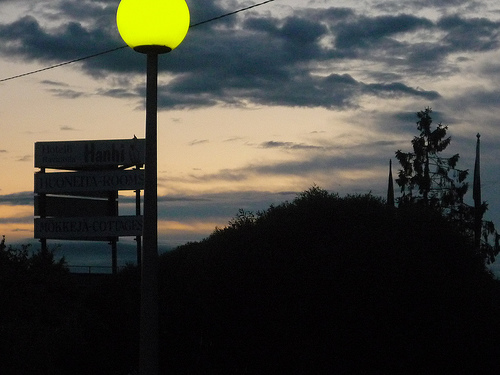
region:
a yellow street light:
[116, 0, 190, 55]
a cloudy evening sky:
[0, 1, 498, 276]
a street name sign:
[34, 215, 145, 237]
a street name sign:
[32, 195, 117, 217]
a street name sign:
[34, 168, 146, 190]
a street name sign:
[33, 141, 147, 166]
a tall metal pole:
[144, 55, 159, 373]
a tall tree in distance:
[397, 108, 498, 270]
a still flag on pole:
[474, 131, 483, 232]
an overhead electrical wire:
[0, 0, 268, 81]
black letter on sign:
[83, 140, 97, 164]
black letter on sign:
[93, 148, 103, 163]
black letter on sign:
[101, 146, 110, 163]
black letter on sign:
[109, 140, 119, 165]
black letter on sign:
[118, 140, 125, 162]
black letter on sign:
[38, 174, 48, 189]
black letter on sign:
[88, 171, 98, 191]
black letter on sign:
[102, 172, 113, 190]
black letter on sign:
[109, 170, 119, 190]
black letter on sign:
[117, 171, 130, 188]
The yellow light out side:
[109, 2, 195, 51]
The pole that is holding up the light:
[121, 47, 174, 261]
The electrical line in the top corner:
[4, 0, 336, 92]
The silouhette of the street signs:
[32, 128, 163, 265]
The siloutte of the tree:
[393, 109, 478, 233]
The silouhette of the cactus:
[453, 119, 487, 247]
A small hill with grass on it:
[9, 188, 498, 364]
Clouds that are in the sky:
[69, 0, 470, 100]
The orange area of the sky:
[13, 149, 326, 247]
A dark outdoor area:
[11, 10, 498, 366]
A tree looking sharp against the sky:
[395, 107, 497, 262]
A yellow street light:
[115, 1, 188, 47]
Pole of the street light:
[143, 51, 155, 284]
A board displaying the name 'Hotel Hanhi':
[30, 135, 145, 165]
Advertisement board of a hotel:
[30, 137, 145, 237]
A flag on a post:
[470, 130, 475, 210]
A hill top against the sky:
[0, 185, 495, 370]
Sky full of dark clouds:
[0, 0, 495, 240]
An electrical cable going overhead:
[0, 0, 266, 80]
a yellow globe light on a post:
[112, 0, 192, 374]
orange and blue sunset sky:
[3, 5, 498, 276]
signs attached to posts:
[24, 129, 149, 286]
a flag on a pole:
[468, 130, 489, 260]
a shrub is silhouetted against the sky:
[385, 95, 497, 275]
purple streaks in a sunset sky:
[3, 177, 290, 249]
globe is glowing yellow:
[111, 0, 193, 60]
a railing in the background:
[53, 258, 120, 280]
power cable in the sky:
[4, 0, 284, 90]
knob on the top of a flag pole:
[473, 126, 485, 143]